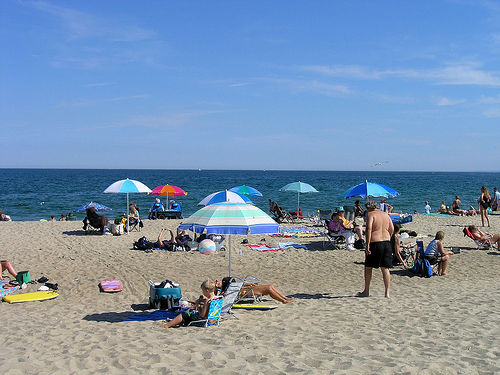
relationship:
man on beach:
[357, 201, 394, 299] [0, 212, 498, 373]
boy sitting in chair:
[159, 280, 219, 330] [176, 292, 232, 338]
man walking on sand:
[357, 201, 394, 299] [300, 307, 442, 349]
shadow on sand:
[282, 288, 364, 303] [0, 210, 497, 371]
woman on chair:
[427, 229, 454, 276] [413, 236, 445, 277]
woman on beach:
[478, 182, 493, 226] [0, 212, 498, 373]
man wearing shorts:
[357, 201, 394, 299] [356, 233, 402, 271]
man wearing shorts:
[357, 201, 394, 299] [358, 240, 394, 268]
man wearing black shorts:
[353, 196, 398, 302] [364, 238, 400, 270]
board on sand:
[1, 288, 61, 305] [0, 210, 497, 371]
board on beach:
[99, 279, 123, 292] [35, 331, 485, 363]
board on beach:
[232, 301, 277, 311] [35, 331, 485, 363]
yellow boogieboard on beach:
[4, 288, 56, 303] [0, 212, 498, 373]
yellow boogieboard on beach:
[234, 299, 277, 311] [0, 212, 498, 373]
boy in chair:
[159, 280, 219, 330] [183, 294, 222, 328]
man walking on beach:
[357, 201, 394, 299] [0, 212, 498, 373]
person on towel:
[151, 221, 180, 258] [116, 227, 216, 264]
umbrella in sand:
[178, 199, 278, 277] [0, 210, 497, 371]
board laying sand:
[93, 276, 128, 294] [0, 210, 497, 371]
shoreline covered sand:
[9, 214, 484, 374] [278, 326, 480, 365]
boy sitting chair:
[156, 274, 225, 334] [192, 297, 227, 332]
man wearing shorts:
[357, 201, 394, 299] [362, 230, 388, 266]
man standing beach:
[357, 201, 394, 299] [3, 53, 498, 372]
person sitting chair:
[417, 229, 457, 276] [203, 295, 222, 326]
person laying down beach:
[211, 279, 291, 304] [0, 212, 498, 373]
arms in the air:
[158, 228, 176, 246] [153, 224, 176, 242]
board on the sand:
[0, 285, 64, 305] [10, 303, 66, 307]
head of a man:
[360, 197, 382, 214] [357, 195, 404, 297]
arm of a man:
[361, 210, 375, 260] [348, 197, 399, 296]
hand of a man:
[364, 243, 374, 255] [353, 196, 398, 302]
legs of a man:
[351, 265, 399, 304] [354, 202, 394, 299]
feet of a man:
[356, 290, 393, 300] [354, 202, 394, 299]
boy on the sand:
[159, 280, 219, 330] [0, 210, 497, 371]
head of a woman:
[436, 230, 443, 240] [425, 230, 453, 275]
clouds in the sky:
[296, 55, 484, 96] [0, 1, 497, 171]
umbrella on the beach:
[102, 177, 153, 236] [0, 212, 498, 373]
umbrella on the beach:
[278, 180, 320, 220] [0, 212, 498, 373]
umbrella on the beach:
[178, 199, 278, 277] [0, 212, 498, 373]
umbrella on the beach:
[338, 180, 401, 206] [0, 212, 498, 373]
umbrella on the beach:
[198, 190, 245, 206] [0, 212, 498, 373]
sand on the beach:
[0, 210, 497, 371] [8, 218, 485, 364]